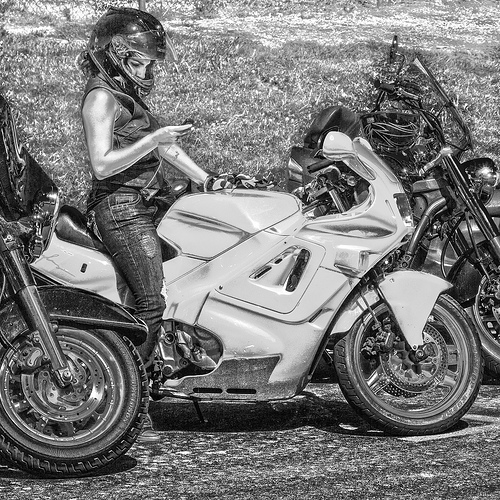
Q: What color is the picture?
A: Black and white.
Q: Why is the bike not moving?
A: It is parked.